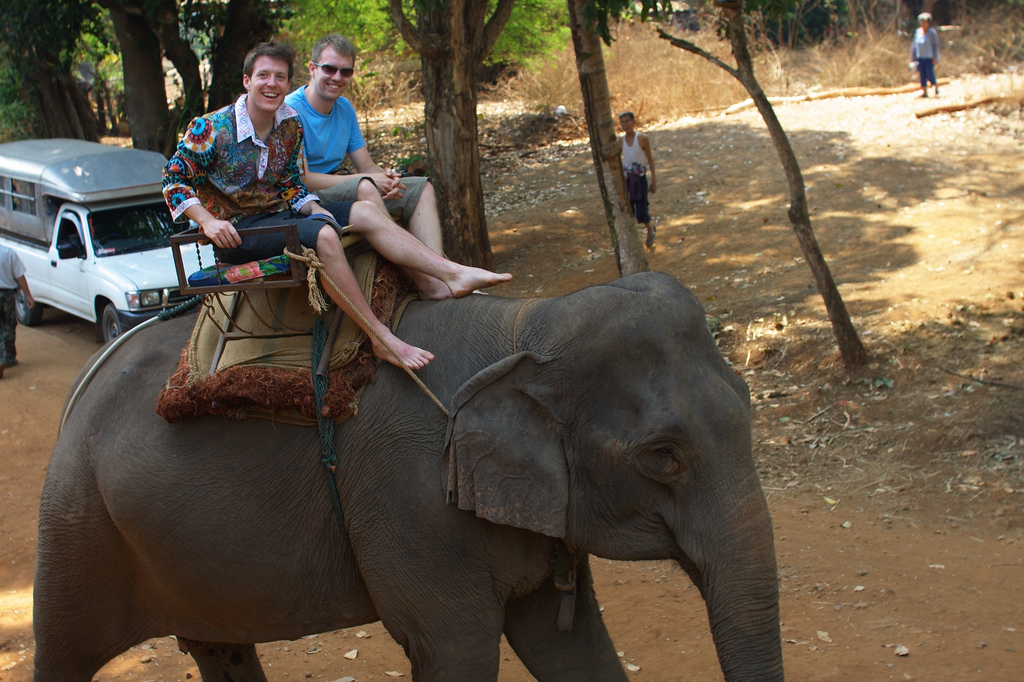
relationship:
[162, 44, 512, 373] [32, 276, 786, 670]
man riding elephant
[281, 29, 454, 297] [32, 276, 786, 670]
man riding elephant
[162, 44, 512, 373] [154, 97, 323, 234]
man wearing shirt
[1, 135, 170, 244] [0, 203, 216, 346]
camper shell on truck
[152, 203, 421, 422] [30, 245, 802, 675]
seat on elephant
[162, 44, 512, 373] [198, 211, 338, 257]
man wearing shorts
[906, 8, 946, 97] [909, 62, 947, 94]
woman wearing pants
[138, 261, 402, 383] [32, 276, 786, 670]
fabric on elephant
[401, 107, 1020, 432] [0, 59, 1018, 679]
shadow on ground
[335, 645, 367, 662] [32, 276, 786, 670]
leaf by elephant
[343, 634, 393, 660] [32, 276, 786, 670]
leaf by elephant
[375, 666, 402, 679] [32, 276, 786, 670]
leaf by elephant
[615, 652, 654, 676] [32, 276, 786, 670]
leaf by elephant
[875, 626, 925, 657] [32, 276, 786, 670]
leaf by elephant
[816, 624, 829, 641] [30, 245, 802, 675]
leaf by elephant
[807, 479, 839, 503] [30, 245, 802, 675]
leaf by elephant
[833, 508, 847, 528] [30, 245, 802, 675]
leaf by elephant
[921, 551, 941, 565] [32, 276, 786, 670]
leaf by elephant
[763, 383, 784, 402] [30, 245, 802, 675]
leaf by elephant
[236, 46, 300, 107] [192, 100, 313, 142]
head above shoulders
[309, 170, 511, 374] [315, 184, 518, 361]
legs below man